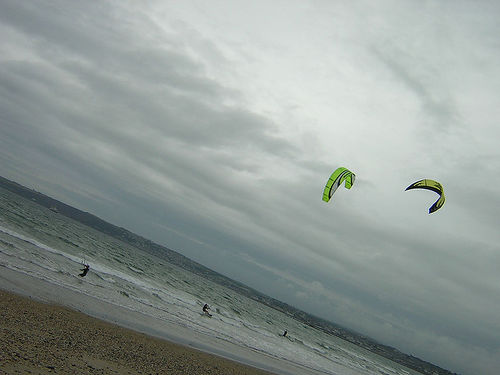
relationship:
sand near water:
[14, 317, 181, 372] [1, 180, 178, 303]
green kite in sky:
[315, 163, 362, 206] [296, 107, 416, 186]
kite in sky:
[408, 176, 448, 216] [2, 0, 499, 365]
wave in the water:
[11, 228, 193, 304] [1, 177, 421, 373]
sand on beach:
[14, 317, 181, 372] [8, 232, 306, 372]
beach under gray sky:
[1, 276, 325, 374] [1, 1, 499, 373]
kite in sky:
[318, 169, 360, 203] [126, 93, 240, 221]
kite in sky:
[408, 176, 448, 216] [126, 93, 240, 221]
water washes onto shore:
[49, 266, 182, 311] [0, 291, 257, 373]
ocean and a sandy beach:
[2, 173, 499, 341] [2, 291, 493, 373]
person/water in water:
[75, 260, 95, 280] [51, 210, 114, 250]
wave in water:
[97, 272, 184, 318] [113, 249, 169, 283]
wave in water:
[3, 217, 344, 373] [1, 177, 421, 373]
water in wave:
[1, 177, 421, 373] [20, 231, 54, 254]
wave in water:
[225, 304, 242, 320] [5, 170, 402, 367]